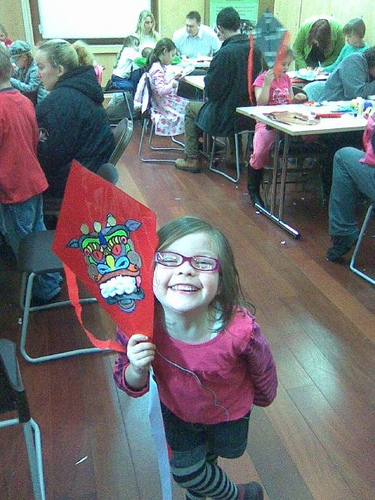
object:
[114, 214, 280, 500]
girl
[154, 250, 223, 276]
glasses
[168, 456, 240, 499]
socks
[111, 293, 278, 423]
shirt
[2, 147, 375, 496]
floors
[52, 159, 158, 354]
kite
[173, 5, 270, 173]
man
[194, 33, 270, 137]
jacket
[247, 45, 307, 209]
girl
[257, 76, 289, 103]
pink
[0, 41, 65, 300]
boy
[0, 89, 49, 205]
shirt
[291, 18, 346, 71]
adult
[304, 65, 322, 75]
green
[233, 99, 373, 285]
table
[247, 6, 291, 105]
kite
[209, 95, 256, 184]
chair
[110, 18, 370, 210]
kids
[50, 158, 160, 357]
adults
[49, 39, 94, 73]
hair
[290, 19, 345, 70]
jacket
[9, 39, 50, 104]
girl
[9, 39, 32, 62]
cap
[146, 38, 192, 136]
girl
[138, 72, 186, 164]
chair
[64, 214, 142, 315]
design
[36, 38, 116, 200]
woman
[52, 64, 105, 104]
hood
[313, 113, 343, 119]
tool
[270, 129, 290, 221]
legs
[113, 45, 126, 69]
braid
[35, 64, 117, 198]
jacket